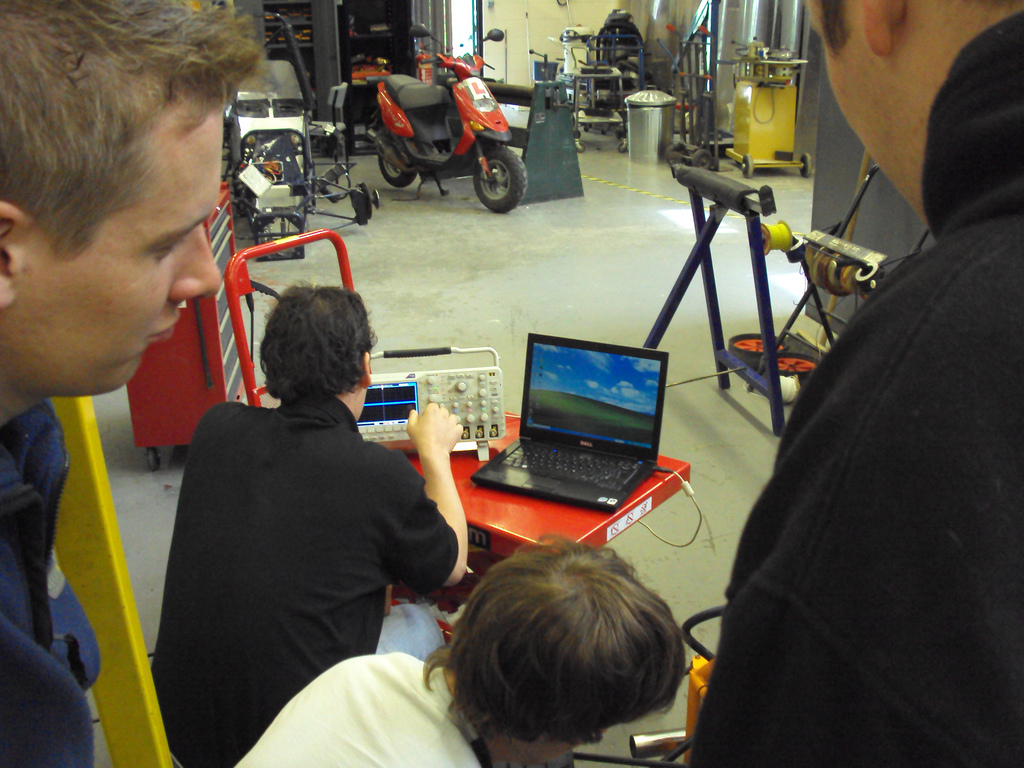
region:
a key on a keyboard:
[534, 439, 548, 452]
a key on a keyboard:
[516, 456, 521, 467]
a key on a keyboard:
[526, 463, 545, 480]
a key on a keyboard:
[550, 475, 558, 477]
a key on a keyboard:
[579, 475, 587, 486]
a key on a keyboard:
[603, 472, 610, 486]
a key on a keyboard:
[611, 465, 621, 475]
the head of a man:
[20, 16, 271, 428]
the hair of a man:
[105, 28, 233, 115]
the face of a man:
[99, 160, 230, 408]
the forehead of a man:
[125, 122, 206, 215]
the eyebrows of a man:
[122, 209, 215, 258]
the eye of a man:
[137, 230, 204, 282]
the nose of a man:
[157, 236, 238, 314]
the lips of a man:
[149, 315, 204, 350]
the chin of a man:
[96, 361, 160, 407]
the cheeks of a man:
[52, 265, 154, 349]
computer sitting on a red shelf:
[480, 335, 667, 520]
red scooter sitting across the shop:
[350, 25, 537, 222]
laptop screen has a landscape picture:
[527, 339, 664, 442]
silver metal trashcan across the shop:
[608, 82, 676, 171]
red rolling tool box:
[115, 253, 261, 443]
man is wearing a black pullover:
[134, 397, 445, 727]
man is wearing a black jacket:
[662, 51, 1017, 674]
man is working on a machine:
[204, 282, 518, 630]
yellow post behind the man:
[33, 398, 227, 756]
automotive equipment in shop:
[346, 336, 512, 454]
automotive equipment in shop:
[620, 153, 783, 441]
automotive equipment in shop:
[729, 226, 888, 375]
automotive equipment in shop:
[577, 99, 622, 147]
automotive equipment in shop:
[719, 33, 815, 180]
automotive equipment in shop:
[664, 0, 725, 187]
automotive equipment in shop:
[590, 2, 645, 100]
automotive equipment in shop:
[545, 17, 581, 79]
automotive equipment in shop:
[244, 124, 315, 264]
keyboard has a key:
[524, 442, 532, 452]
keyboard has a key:
[551, 453, 564, 466]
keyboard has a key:
[568, 450, 576, 461]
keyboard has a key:
[577, 453, 590, 463]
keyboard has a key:
[593, 457, 603, 467]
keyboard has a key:
[603, 457, 614, 467]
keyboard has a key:
[590, 466, 601, 476]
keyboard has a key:
[567, 458, 577, 469]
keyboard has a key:
[538, 457, 546, 467]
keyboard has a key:
[524, 453, 531, 463]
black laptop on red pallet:
[460, 309, 688, 507]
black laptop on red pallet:
[459, 298, 674, 517]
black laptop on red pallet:
[457, 293, 680, 531]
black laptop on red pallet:
[466, 309, 681, 519]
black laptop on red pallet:
[453, 306, 688, 525]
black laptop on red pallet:
[456, 306, 676, 532]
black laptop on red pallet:
[460, 312, 685, 537]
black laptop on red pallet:
[463, 304, 685, 524]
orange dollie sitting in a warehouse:
[224, 230, 693, 641]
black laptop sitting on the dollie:
[478, 334, 671, 508]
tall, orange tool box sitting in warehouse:
[119, 179, 257, 464]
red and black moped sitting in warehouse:
[372, 25, 527, 207]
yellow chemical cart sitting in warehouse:
[726, 34, 812, 175]